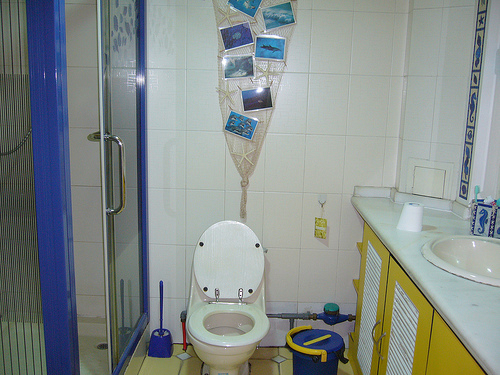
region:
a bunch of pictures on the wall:
[214, 2, 288, 202]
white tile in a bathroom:
[312, 70, 389, 175]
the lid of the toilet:
[195, 214, 265, 296]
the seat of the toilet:
[173, 306, 270, 351]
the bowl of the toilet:
[199, 346, 250, 372]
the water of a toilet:
[210, 316, 240, 337]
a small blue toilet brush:
[145, 278, 175, 362]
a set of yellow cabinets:
[336, 231, 438, 361]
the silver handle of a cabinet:
[355, 308, 406, 370]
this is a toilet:
[177, 220, 277, 373]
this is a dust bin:
[286, 314, 357, 371]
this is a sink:
[426, 215, 496, 299]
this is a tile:
[307, 67, 345, 139]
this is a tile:
[347, 70, 397, 141]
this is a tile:
[306, 131, 350, 196]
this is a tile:
[146, 64, 184, 124]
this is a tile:
[260, 192, 304, 243]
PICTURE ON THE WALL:
[241, 89, 274, 111]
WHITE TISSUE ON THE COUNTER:
[401, 203, 421, 231]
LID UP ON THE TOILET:
[213, 224, 245, 293]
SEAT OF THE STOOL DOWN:
[198, 305, 268, 348]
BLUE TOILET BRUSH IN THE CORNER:
[153, 279, 173, 356]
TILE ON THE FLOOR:
[263, 357, 275, 369]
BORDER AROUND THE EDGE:
[463, 62, 474, 145]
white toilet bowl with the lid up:
[171, 220, 271, 374]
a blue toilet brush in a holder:
[147, 269, 171, 361]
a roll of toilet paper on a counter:
[394, 193, 431, 240]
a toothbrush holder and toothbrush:
[458, 186, 494, 235]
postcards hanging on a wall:
[210, 4, 299, 171]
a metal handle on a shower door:
[92, 118, 127, 249]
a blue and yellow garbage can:
[281, 315, 348, 369]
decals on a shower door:
[105, 11, 137, 71]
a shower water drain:
[90, 331, 107, 355]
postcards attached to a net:
[201, 10, 298, 168]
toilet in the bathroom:
[186, 212, 286, 364]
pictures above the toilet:
[199, 0, 291, 195]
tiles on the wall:
[313, 18, 380, 128]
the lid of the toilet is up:
[192, 219, 269, 304]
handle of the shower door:
[108, 128, 130, 212]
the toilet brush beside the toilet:
[151, 271, 183, 354]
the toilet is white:
[180, 220, 277, 362]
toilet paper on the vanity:
[391, 197, 425, 239]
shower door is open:
[91, 2, 170, 362]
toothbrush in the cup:
[466, 178, 483, 205]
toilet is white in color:
[161, 215, 271, 370]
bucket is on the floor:
[288, 326, 346, 373]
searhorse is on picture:
[465, 183, 497, 240]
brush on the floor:
[142, 281, 179, 353]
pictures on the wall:
[221, 12, 292, 194]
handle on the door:
[77, 108, 145, 232]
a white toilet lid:
[192, 211, 270, 296]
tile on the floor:
[134, 350, 206, 373]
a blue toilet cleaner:
[140, 276, 176, 356]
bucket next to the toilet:
[280, 317, 350, 373]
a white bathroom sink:
[418, 225, 492, 300]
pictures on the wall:
[198, 10, 305, 170]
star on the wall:
[229, 140, 259, 173]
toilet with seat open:
[170, 212, 287, 368]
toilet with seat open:
[184, 202, 281, 370]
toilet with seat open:
[172, 213, 282, 365]